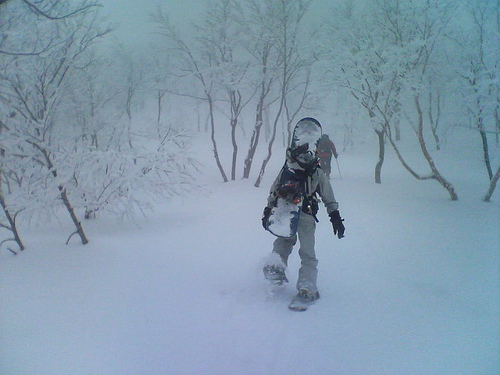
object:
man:
[261, 142, 346, 303]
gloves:
[327, 210, 345, 241]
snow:
[0, 101, 500, 375]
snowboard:
[284, 290, 319, 313]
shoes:
[297, 284, 323, 304]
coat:
[268, 160, 339, 214]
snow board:
[262, 116, 324, 239]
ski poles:
[333, 154, 346, 182]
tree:
[329, 0, 413, 182]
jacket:
[315, 135, 338, 161]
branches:
[23, 1, 103, 22]